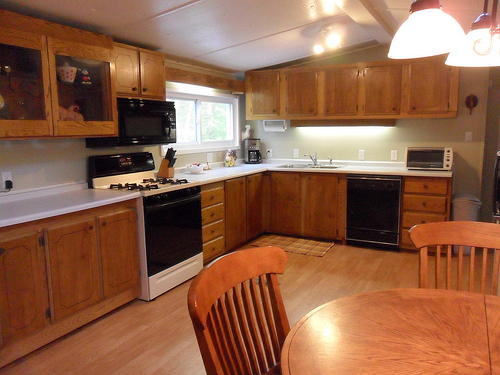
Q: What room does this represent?
A: It represents the kitchen.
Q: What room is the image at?
A: It is at the kitchen.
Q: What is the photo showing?
A: It is showing a kitchen.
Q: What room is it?
A: It is a kitchen.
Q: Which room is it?
A: It is a kitchen.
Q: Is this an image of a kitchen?
A: Yes, it is showing a kitchen.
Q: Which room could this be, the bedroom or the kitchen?
A: It is the kitchen.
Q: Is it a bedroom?
A: No, it is a kitchen.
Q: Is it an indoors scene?
A: Yes, it is indoors.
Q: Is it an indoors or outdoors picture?
A: It is indoors.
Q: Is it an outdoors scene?
A: No, it is indoors.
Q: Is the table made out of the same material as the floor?
A: Yes, both the table and the floor are made of wood.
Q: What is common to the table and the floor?
A: The material, both the table and the floor are wooden.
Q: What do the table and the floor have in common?
A: The material, both the table and the floor are wooden.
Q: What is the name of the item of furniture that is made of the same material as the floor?
A: The piece of furniture is a table.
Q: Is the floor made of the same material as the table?
A: Yes, both the floor and the table are made of wood.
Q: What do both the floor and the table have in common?
A: The material, both the floor and the table are wooden.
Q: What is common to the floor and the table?
A: The material, both the floor and the table are wooden.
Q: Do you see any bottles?
A: No, there are no bottles.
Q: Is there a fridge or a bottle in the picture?
A: No, there are no bottles or refrigerators.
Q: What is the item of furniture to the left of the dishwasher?
A: The piece of furniture is a drawer.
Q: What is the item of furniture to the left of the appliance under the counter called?
A: The piece of furniture is a drawer.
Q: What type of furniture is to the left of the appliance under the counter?
A: The piece of furniture is a drawer.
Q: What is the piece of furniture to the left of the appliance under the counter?
A: The piece of furniture is a drawer.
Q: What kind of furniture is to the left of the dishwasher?
A: The piece of furniture is a drawer.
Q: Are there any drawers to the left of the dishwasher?
A: Yes, there is a drawer to the left of the dishwasher.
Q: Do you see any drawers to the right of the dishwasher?
A: No, the drawer is to the left of the dishwasher.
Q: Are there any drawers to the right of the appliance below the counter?
A: No, the drawer is to the left of the dishwasher.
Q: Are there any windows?
A: Yes, there is a window.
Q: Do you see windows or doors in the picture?
A: Yes, there is a window.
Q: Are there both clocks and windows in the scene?
A: No, there is a window but no clocks.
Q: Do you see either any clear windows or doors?
A: Yes, there is a clear window.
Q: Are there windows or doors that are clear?
A: Yes, the window is clear.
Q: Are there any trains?
A: No, there are no trains.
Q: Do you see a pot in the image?
A: No, there are no pots.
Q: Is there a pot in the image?
A: No, there are no pots.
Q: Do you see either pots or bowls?
A: No, there are no pots or bowls.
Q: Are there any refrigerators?
A: No, there are no refrigerators.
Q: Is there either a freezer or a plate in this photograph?
A: No, there are no refrigerators or plates.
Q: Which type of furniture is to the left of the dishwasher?
A: The piece of furniture is a drawer.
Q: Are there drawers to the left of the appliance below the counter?
A: Yes, there is a drawer to the left of the dishwasher.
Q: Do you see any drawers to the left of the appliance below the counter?
A: Yes, there is a drawer to the left of the dishwasher.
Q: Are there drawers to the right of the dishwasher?
A: No, the drawer is to the left of the dishwasher.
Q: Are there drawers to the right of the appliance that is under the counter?
A: No, the drawer is to the left of the dishwasher.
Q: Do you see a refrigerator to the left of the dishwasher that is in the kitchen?
A: No, there is a drawer to the left of the dishwasher.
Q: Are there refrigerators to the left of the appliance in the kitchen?
A: No, there is a drawer to the left of the dishwasher.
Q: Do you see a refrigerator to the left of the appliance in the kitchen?
A: No, there is a drawer to the left of the dishwasher.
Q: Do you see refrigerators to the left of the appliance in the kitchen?
A: No, there is a drawer to the left of the dishwasher.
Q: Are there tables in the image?
A: Yes, there is a table.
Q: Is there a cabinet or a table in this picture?
A: Yes, there is a table.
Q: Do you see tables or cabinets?
A: Yes, there is a table.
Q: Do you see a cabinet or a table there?
A: Yes, there is a table.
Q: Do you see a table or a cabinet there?
A: Yes, there is a table.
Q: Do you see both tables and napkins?
A: No, there is a table but no napkins.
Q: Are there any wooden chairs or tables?
A: Yes, there is a wood table.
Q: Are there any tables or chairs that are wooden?
A: Yes, the table is wooden.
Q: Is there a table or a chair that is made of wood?
A: Yes, the table is made of wood.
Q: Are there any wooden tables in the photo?
A: Yes, there is a wood table.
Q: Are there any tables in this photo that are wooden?
A: Yes, there is a table that is wooden.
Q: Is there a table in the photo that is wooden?
A: Yes, there is a table that is wooden.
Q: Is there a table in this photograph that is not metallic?
A: Yes, there is a wooden table.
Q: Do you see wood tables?
A: Yes, there is a table that is made of wood.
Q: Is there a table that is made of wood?
A: Yes, there is a table that is made of wood.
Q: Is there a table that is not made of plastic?
A: Yes, there is a table that is made of wood.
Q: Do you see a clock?
A: No, there are no clocks.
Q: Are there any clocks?
A: No, there are no clocks.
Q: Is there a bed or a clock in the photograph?
A: No, there are no clocks or beds.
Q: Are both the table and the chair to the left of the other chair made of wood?
A: Yes, both the table and the chair are made of wood.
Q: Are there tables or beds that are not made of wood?
A: No, there is a table but it is made of wood.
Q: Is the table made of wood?
A: Yes, the table is made of wood.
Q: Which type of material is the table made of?
A: The table is made of wood.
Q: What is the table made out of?
A: The table is made of wood.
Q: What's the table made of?
A: The table is made of wood.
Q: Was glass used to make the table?
A: No, the table is made of wood.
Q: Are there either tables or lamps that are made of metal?
A: No, there is a table but it is made of wood.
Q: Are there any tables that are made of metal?
A: No, there is a table but it is made of wood.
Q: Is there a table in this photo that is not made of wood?
A: No, there is a table but it is made of wood.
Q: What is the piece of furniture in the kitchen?
A: The piece of furniture is a table.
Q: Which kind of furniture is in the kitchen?
A: The piece of furniture is a table.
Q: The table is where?
A: The table is in the kitchen.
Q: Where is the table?
A: The table is in the kitchen.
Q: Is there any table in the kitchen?
A: Yes, there is a table in the kitchen.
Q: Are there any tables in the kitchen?
A: Yes, there is a table in the kitchen.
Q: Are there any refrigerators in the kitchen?
A: No, there is a table in the kitchen.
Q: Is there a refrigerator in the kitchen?
A: No, there is a table in the kitchen.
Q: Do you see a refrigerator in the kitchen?
A: No, there is a table in the kitchen.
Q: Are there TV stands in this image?
A: No, there are no TV stands.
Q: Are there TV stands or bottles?
A: No, there are no TV stands or bottles.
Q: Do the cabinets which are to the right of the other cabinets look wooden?
A: Yes, the cabinets are wooden.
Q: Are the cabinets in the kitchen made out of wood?
A: Yes, the cabinets are made of wood.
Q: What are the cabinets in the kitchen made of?
A: The cabinets are made of wood.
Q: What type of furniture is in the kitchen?
A: The pieces of furniture are cabinets.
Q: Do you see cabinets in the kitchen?
A: Yes, there are cabinets in the kitchen.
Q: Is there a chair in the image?
A: Yes, there is a chair.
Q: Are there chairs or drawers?
A: Yes, there is a chair.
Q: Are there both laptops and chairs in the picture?
A: No, there is a chair but no laptops.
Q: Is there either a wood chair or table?
A: Yes, there is a wood chair.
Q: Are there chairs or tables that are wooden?
A: Yes, the chair is wooden.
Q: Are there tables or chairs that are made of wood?
A: Yes, the chair is made of wood.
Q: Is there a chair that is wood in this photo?
A: Yes, there is a wood chair.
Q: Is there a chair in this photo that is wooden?
A: Yes, there is a chair that is wooden.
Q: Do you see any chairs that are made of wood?
A: Yes, there is a chair that is made of wood.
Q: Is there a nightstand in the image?
A: No, there are no nightstands.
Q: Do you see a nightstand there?
A: No, there are no nightstands.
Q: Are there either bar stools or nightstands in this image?
A: No, there are no nightstands or bar stools.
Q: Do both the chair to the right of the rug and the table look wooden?
A: Yes, both the chair and the table are wooden.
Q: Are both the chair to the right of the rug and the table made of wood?
A: Yes, both the chair and the table are made of wood.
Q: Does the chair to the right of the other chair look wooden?
A: Yes, the chair is wooden.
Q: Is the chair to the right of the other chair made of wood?
A: Yes, the chair is made of wood.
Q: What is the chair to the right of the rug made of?
A: The chair is made of wood.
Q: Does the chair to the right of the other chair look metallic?
A: No, the chair is wooden.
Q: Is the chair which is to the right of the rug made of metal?
A: No, the chair is made of wood.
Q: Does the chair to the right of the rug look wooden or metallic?
A: The chair is wooden.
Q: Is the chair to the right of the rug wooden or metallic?
A: The chair is wooden.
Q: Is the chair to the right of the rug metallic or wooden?
A: The chair is wooden.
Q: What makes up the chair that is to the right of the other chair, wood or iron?
A: The chair is made of wood.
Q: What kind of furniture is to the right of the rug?
A: The piece of furniture is a chair.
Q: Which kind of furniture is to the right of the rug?
A: The piece of furniture is a chair.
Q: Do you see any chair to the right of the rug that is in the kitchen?
A: Yes, there is a chair to the right of the rug.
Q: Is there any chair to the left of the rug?
A: No, the chair is to the right of the rug.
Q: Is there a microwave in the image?
A: Yes, there is a microwave.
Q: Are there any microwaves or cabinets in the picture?
A: Yes, there is a microwave.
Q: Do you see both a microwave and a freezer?
A: No, there is a microwave but no refrigerators.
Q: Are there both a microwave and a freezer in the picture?
A: No, there is a microwave but no refrigerators.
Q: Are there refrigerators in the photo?
A: No, there are no refrigerators.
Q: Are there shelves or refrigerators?
A: No, there are no refrigerators or shelves.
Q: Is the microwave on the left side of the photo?
A: Yes, the microwave is on the left of the image.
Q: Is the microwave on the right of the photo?
A: No, the microwave is on the left of the image.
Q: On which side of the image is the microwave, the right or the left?
A: The microwave is on the left of the image.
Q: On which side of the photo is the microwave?
A: The microwave is on the left of the image.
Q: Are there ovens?
A: Yes, there is an oven.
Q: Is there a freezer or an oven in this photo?
A: Yes, there is an oven.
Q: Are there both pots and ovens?
A: No, there is an oven but no pots.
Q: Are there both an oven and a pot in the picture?
A: No, there is an oven but no pots.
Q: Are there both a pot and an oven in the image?
A: No, there is an oven but no pots.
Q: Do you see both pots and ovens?
A: No, there is an oven but no pots.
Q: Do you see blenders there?
A: No, there are no blenders.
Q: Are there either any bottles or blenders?
A: No, there are no blenders or bottles.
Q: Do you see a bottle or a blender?
A: No, there are no blenders or bottles.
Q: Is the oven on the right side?
A: Yes, the oven is on the right of the image.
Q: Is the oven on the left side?
A: No, the oven is on the right of the image.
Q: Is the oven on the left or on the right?
A: The oven is on the right of the image.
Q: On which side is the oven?
A: The oven is on the right of the image.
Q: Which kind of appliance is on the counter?
A: The appliance is an oven.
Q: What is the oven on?
A: The oven is on the counter.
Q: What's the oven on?
A: The oven is on the counter.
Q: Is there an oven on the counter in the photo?
A: Yes, there is an oven on the counter.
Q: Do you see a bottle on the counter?
A: No, there is an oven on the counter.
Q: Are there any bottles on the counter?
A: No, there is an oven on the counter.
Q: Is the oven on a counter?
A: Yes, the oven is on a counter.